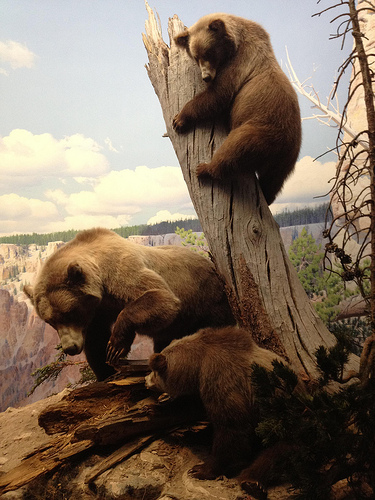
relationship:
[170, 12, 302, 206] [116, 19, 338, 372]
bear on tree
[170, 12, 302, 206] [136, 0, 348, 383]
bear on tree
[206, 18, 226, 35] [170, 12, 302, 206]
ear of bear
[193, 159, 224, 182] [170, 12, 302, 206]
paw of bear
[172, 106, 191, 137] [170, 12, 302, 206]
paw of bear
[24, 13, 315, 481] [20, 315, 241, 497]
bears on rocks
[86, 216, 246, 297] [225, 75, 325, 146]
back of bear